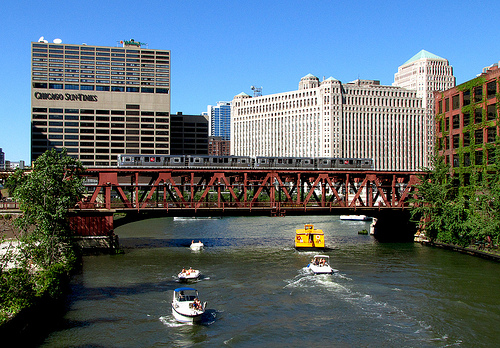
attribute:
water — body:
[123, 225, 483, 345]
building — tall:
[25, 32, 175, 169]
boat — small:
[165, 280, 209, 327]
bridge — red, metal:
[0, 165, 437, 214]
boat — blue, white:
[158, 288, 225, 321]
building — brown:
[429, 61, 499, 231]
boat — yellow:
[296, 222, 326, 250]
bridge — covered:
[76, 152, 427, 224]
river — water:
[1, 211, 498, 346]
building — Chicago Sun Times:
[32, 54, 157, 174]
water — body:
[230, 273, 487, 338]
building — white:
[214, 79, 455, 185]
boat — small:
[173, 263, 203, 281]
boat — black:
[160, 280, 209, 338]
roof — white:
[165, 261, 211, 285]